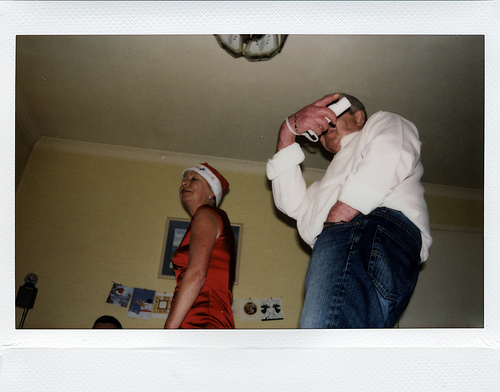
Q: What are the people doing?
A: Playing video game.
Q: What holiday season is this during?
A: Christmas.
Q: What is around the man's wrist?
A: A wii remote.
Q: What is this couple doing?
A: Playing a wii game.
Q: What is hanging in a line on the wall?
A: Holiday cards.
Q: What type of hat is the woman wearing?
A: A holiday stocking hat.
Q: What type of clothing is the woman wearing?
A: A red dress.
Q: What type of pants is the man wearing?
A: Blue jeans.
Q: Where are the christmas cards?
A: On the wall.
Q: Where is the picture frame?
A: Hanging on the wall.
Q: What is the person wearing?
A: Blue jeans.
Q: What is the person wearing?
A: Long sleeve shirt.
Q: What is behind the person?
A: Pictures.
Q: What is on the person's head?
A: Christmas hat.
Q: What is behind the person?
A: Pictures.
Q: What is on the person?
A: Santa hat.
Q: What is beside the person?
A: Photos on string.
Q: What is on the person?
A: White shirt.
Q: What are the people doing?
A: Playing game.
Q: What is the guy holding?
A: A video game controller.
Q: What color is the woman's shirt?
A: Red.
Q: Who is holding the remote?
A: The man.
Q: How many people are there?
A: Two.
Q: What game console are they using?
A: Wii.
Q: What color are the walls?
A: Light yellow.